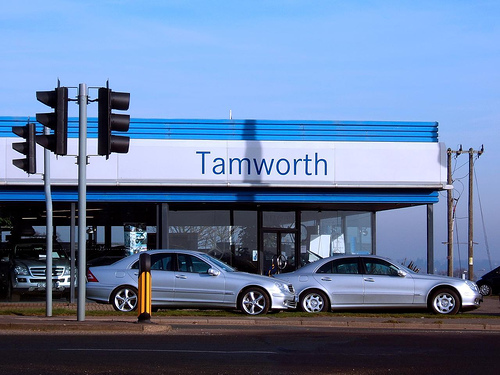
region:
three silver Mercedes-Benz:
[11, 240, 482, 312]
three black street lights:
[10, 77, 135, 167]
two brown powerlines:
[440, 131, 485, 286]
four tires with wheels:
[100, 282, 460, 317]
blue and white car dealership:
[0, 116, 440, 271]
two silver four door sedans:
[85, 248, 485, 309]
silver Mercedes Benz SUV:
[10, 240, 75, 295]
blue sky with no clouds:
[0, 0, 495, 280]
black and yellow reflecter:
[135, 250, 150, 320]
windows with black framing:
[161, 200, 373, 272]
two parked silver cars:
[76, 241, 498, 336]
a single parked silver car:
[65, 230, 307, 330]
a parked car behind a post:
[82, 239, 301, 330]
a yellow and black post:
[102, 247, 185, 330]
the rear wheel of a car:
[115, 281, 141, 327]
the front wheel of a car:
[224, 282, 277, 326]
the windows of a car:
[130, 249, 219, 291]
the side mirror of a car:
[198, 261, 223, 287]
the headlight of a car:
[11, 260, 44, 292]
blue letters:
[182, 140, 381, 200]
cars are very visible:
[101, 176, 493, 373]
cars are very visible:
[76, 198, 351, 353]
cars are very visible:
[136, 247, 346, 368]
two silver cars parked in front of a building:
[78, 255, 476, 345]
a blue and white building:
[2, 97, 447, 233]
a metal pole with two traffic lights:
[39, 55, 129, 328]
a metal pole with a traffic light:
[21, 115, 54, 358]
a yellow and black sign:
[130, 242, 155, 324]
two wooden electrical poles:
[436, 130, 486, 295]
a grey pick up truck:
[3, 217, 75, 319]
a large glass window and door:
[152, 198, 376, 279]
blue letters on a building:
[153, 132, 348, 202]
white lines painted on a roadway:
[11, 321, 449, 373]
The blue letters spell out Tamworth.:
[180, 138, 355, 179]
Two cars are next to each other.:
[73, 222, 496, 317]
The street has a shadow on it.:
[10, 320, 496, 368]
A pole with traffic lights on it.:
[30, 73, 135, 320]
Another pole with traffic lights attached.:
[5, 105, 65, 326]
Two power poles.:
[440, 135, 485, 281]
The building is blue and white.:
[0, 96, 448, 276]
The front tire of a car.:
[422, 280, 462, 316]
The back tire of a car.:
[295, 285, 335, 317]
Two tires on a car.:
[101, 277, 280, 326]